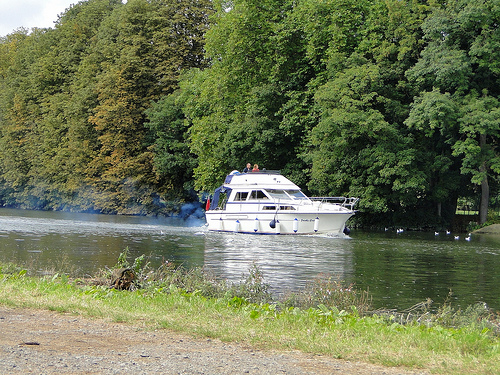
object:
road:
[0, 304, 421, 374]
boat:
[202, 169, 360, 235]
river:
[0, 205, 500, 312]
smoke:
[147, 195, 208, 229]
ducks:
[463, 234, 470, 243]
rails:
[310, 195, 343, 201]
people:
[251, 162, 265, 172]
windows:
[265, 188, 288, 196]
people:
[240, 162, 253, 175]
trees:
[401, 0, 499, 224]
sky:
[0, 0, 83, 39]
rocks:
[22, 342, 47, 347]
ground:
[0, 268, 500, 374]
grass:
[0, 261, 500, 374]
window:
[256, 191, 269, 200]